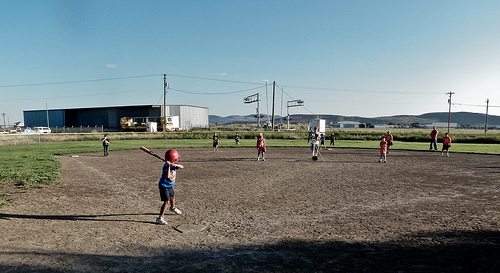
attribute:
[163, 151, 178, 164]
baseball helmet — red, round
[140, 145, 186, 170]
baseball bat — long, brown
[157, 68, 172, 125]
powerline pole — long, cylindrical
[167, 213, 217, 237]
home base — pentagon shaped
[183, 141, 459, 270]
baseball field — tan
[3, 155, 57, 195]
grass — green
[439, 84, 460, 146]
telephone pole — tall, brown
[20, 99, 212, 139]
warehouse — grey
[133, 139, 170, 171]
baseball bat — brown, black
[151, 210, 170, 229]
tennis shoe — small, white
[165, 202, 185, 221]
tennis shoe — small, white